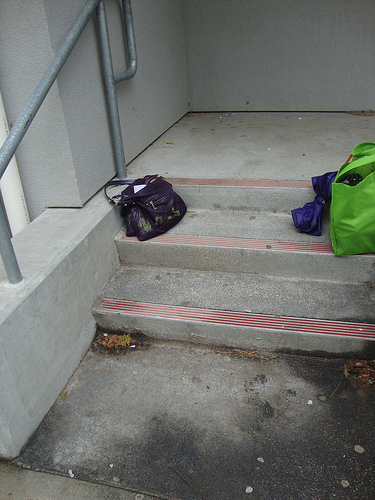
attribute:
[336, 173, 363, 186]
bag — green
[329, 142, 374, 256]
item — black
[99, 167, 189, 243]
purse — purple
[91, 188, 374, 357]
stairs — cement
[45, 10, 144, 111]
railings — metal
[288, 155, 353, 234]
umbrella — blue, tilted, closed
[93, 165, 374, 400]
steps — red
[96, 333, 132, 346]
leaves — dirty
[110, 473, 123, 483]
spot — white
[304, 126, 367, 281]
bag — green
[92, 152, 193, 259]
bag — purple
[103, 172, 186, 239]
purse — black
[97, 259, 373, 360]
stairs — grey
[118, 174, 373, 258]
stairs — grey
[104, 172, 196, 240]
purse — black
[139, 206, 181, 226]
stains — green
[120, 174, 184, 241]
purse — bag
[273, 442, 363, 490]
stain — Dark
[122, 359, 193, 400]
cement — gray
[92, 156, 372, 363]
steps — green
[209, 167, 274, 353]
stairs — cement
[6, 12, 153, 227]
railing — silver , metal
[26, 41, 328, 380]
stairs — small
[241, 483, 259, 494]
spot — white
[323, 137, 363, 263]
tote bag — green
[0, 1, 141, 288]
railing — metal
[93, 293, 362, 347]
treads — red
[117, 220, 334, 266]
treads — red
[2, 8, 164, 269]
rail — metal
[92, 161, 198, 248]
purse — black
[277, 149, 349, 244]
umbrella — blue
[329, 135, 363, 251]
bag — grocery, fabric, green